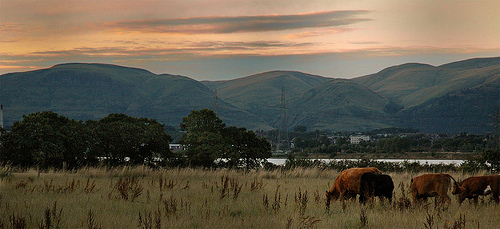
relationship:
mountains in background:
[0, 62, 496, 134] [1, 1, 498, 157]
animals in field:
[325, 167, 499, 206] [0, 170, 495, 228]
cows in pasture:
[325, 167, 499, 206] [0, 170, 495, 228]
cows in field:
[325, 167, 499, 206] [0, 170, 495, 228]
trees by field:
[3, 115, 269, 164] [0, 170, 495, 228]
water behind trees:
[94, 153, 498, 168] [3, 115, 269, 164]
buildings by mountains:
[350, 134, 370, 145] [0, 62, 496, 134]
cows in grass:
[325, 167, 499, 206] [0, 170, 495, 228]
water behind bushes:
[94, 153, 498, 168] [79, 159, 498, 171]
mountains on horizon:
[0, 62, 496, 134] [1, 1, 498, 157]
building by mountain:
[350, 134, 370, 145] [0, 62, 496, 134]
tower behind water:
[275, 84, 290, 152] [94, 153, 498, 168]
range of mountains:
[0, 60, 498, 133] [0, 62, 496, 134]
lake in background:
[156, 159, 498, 169] [1, 1, 498, 157]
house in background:
[350, 134, 370, 145] [1, 1, 498, 157]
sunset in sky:
[0, 1, 67, 75] [1, 0, 498, 78]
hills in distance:
[0, 62, 496, 134] [1, 1, 498, 157]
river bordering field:
[94, 153, 498, 168] [0, 170, 495, 228]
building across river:
[350, 134, 370, 145] [94, 153, 498, 168]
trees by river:
[3, 115, 269, 164] [94, 153, 498, 168]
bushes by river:
[79, 159, 498, 171] [94, 153, 498, 168]